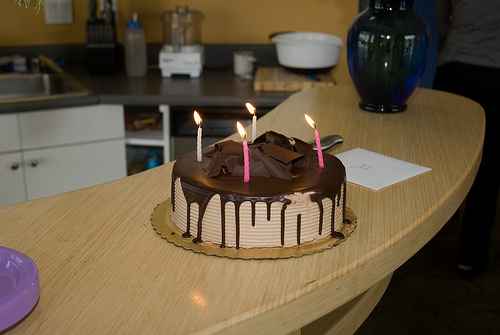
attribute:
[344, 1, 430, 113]
vase — large, blue, glass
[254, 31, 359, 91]
bowl — white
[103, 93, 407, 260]
cake — WHITE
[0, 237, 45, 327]
plastic plates — purple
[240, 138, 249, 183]
candle — pink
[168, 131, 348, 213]
icing — CREAM COLORED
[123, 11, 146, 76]
baby bottle — BLUE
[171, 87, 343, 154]
candles — lit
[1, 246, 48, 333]
plates — Purple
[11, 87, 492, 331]
table — white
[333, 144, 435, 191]
envelope — white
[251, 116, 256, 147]
candle — WHITE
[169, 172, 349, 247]
drizzle — CHOCOLATE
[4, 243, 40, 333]
plates — PURPLE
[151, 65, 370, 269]
cake — chocolate, shavings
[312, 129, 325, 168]
candle — PINK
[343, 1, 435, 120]
vase — blue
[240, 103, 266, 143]
candle — white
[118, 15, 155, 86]
drinking bottle — plastic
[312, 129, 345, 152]
handle — silver, metal